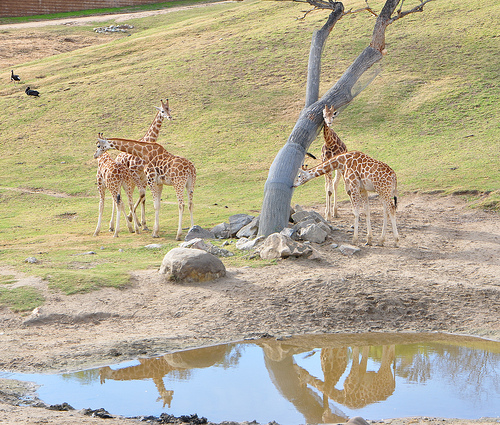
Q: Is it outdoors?
A: Yes, it is outdoors.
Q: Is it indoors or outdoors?
A: It is outdoors.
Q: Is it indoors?
A: No, it is outdoors.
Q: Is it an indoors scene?
A: No, it is outdoors.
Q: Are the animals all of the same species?
A: No, there are both giraffes and birds.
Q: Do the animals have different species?
A: Yes, they are giraffes and birds.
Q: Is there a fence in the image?
A: No, there are no fences.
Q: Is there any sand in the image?
A: Yes, there is sand.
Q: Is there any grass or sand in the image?
A: Yes, there is sand.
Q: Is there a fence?
A: No, there are no fences.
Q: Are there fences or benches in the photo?
A: No, there are no fences or benches.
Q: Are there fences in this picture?
A: No, there are no fences.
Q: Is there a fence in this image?
A: No, there are no fences.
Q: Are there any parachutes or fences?
A: No, there are no fences or parachutes.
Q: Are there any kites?
A: No, there are no kites.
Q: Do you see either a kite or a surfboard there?
A: No, there are no kites or surfboards.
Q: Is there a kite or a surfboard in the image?
A: No, there are no kites or surfboards.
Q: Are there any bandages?
A: No, there are no bandages.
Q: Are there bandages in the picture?
A: No, there are no bandages.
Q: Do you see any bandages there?
A: No, there are no bandages.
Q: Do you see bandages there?
A: No, there are no bandages.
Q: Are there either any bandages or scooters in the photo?
A: No, there are no bandages or scooters.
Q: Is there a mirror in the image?
A: No, there are no mirrors.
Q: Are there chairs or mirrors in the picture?
A: No, there are no mirrors or chairs.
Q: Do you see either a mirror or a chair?
A: No, there are no mirrors or chairs.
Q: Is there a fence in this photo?
A: No, there are no fences.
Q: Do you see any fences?
A: No, there are no fences.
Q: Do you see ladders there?
A: No, there are no ladders.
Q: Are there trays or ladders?
A: No, there are no ladders or trays.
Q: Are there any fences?
A: No, there are no fences.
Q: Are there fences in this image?
A: No, there are no fences.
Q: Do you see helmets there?
A: No, there are no helmets.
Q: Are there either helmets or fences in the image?
A: No, there are no helmets or fences.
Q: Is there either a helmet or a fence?
A: No, there are no helmets or fences.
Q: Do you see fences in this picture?
A: No, there are no fences.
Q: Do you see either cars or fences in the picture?
A: No, there are no fences or cars.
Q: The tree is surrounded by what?
A: The tree is surrounded by the stones.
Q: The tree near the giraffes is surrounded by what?
A: The tree is surrounded by the stones.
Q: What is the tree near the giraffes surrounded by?
A: The tree is surrounded by the stones.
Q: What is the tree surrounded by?
A: The tree is surrounded by the stones.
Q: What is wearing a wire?
A: The tree is wearing a wire.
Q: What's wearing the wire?
A: The tree is wearing a wire.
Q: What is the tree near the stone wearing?
A: The tree is wearing a wire.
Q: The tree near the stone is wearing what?
A: The tree is wearing a wire.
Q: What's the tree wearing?
A: The tree is wearing a wire.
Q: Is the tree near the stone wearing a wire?
A: Yes, the tree is wearing a wire.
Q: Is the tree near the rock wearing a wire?
A: Yes, the tree is wearing a wire.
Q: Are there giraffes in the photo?
A: Yes, there are giraffes.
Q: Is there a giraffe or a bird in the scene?
A: Yes, there are giraffes.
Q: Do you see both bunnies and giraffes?
A: No, there are giraffes but no bunnies.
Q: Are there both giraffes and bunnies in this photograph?
A: No, there are giraffes but no bunnies.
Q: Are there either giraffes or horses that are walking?
A: Yes, the giraffes are walking.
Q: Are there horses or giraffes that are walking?
A: Yes, the giraffes are walking.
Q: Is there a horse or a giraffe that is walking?
A: Yes, the giraffes are walking.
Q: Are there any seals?
A: No, there are no seals.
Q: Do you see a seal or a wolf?
A: No, there are no seals or wolves.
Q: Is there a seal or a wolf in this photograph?
A: No, there are no seals or wolves.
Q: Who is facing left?
A: The giraffes are facing left.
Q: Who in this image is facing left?
A: The giraffes are facing left.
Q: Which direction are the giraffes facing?
A: The giraffes are facing left.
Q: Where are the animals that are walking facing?
A: The giraffes are facing left.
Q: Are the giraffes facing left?
A: Yes, the giraffes are facing left.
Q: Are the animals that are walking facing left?
A: Yes, the giraffes are facing left.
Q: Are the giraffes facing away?
A: No, the giraffes are facing left.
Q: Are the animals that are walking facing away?
A: No, the giraffes are facing left.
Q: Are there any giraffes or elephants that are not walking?
A: No, there are giraffes but they are walking.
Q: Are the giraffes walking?
A: Yes, the giraffes are walking.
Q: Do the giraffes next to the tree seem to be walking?
A: Yes, the giraffes are walking.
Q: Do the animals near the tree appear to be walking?
A: Yes, the giraffes are walking.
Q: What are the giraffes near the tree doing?
A: The giraffes are walking.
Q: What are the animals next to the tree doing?
A: The giraffes are walking.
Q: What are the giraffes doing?
A: The giraffes are walking.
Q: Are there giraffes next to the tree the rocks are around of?
A: Yes, there are giraffes next to the tree.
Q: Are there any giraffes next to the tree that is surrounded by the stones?
A: Yes, there are giraffes next to the tree.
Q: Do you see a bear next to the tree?
A: No, there are giraffes next to the tree.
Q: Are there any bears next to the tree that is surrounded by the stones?
A: No, there are giraffes next to the tree.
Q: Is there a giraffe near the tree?
A: Yes, there are giraffes near the tree.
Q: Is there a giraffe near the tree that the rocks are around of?
A: Yes, there are giraffes near the tree.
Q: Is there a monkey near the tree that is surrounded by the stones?
A: No, there are giraffes near the tree.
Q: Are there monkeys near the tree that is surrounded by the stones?
A: No, there are giraffes near the tree.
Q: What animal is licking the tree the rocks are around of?
A: The giraffes are licking the tree.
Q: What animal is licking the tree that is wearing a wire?
A: The giraffes are licking the tree.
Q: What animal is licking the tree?
A: The giraffes are licking the tree.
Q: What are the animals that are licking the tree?
A: The animals are giraffes.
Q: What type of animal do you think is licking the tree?
A: The animals are giraffes.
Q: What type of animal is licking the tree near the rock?
A: The animals are giraffes.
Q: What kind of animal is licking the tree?
A: The animals are giraffes.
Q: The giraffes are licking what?
A: The giraffes are licking the tree.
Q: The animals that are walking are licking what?
A: The giraffes are licking the tree.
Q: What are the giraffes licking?
A: The giraffes are licking the tree.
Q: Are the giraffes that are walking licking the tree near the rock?
A: Yes, the giraffes are licking the tree.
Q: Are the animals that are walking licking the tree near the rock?
A: Yes, the giraffes are licking the tree.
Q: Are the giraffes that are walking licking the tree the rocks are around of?
A: Yes, the giraffes are licking the tree.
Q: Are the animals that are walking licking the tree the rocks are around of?
A: Yes, the giraffes are licking the tree.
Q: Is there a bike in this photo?
A: No, there are no bikes.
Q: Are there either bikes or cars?
A: No, there are no bikes or cars.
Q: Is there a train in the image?
A: No, there are no trains.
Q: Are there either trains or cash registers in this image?
A: No, there are no trains or cash registers.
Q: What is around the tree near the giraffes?
A: The rocks are around the tree.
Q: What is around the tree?
A: The rocks are around the tree.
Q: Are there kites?
A: No, there are no kites.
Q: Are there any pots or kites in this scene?
A: No, there are no kites or pots.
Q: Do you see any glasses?
A: No, there are no glasses.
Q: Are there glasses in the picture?
A: No, there are no glasses.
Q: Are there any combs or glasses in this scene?
A: No, there are no glasses or combs.